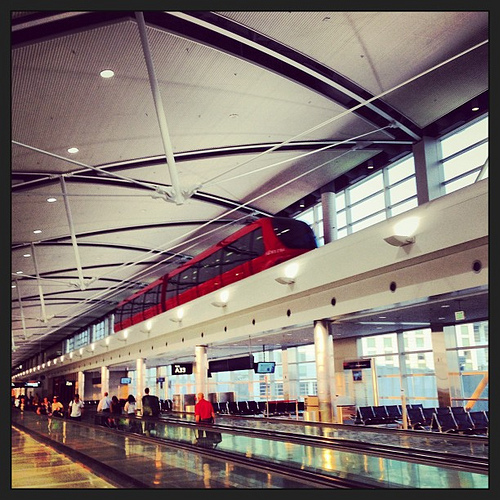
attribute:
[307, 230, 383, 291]
wall — white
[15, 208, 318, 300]
train — red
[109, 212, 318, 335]
carriage — red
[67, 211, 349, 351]
train — big, red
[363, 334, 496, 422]
windows — shut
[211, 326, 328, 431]
tv — big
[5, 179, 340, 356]
train — big, red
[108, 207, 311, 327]
train — red, big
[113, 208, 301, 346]
train — red, big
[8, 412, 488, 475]
belt — large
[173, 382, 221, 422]
shirt — white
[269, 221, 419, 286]
lights — on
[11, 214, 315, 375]
train — red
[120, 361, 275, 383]
monitors — overhead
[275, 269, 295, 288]
fixture — facing upwards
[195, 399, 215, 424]
shirt — red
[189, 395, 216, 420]
shirt — red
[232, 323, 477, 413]
windows — large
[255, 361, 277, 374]
tv — big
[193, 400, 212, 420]
shirt — red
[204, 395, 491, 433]
chairs — blue, lined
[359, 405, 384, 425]
seat — blue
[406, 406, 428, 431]
seat — blue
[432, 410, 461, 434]
seat — blue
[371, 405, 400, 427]
seat — blue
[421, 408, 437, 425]
seat — blue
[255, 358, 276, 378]
monitor — on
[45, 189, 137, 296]
overhead lighting — circular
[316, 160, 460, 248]
windows — closed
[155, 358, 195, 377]
sign — black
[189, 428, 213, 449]
bag — black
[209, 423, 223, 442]
bag — black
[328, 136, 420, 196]
trim — black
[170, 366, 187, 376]
writing — white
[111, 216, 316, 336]
train — red, big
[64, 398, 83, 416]
shirt — white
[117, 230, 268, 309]
windows — closed